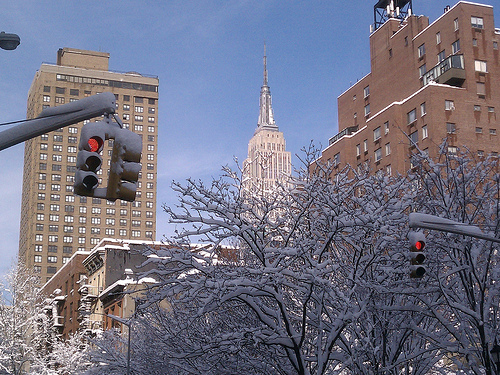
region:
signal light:
[74, 118, 138, 201]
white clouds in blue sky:
[154, 6, 196, 43]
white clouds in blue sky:
[277, 69, 316, 104]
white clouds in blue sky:
[180, 105, 203, 132]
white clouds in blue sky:
[183, 39, 220, 62]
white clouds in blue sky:
[166, 55, 210, 111]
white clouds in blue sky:
[181, 37, 230, 105]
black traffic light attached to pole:
[0, 95, 150, 211]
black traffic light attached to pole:
[407, 217, 498, 282]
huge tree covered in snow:
[141, 154, 389, 373]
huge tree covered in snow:
[313, 162, 453, 372]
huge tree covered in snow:
[41, 334, 88, 371]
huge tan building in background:
[230, 33, 292, 248]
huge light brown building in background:
[11, 48, 158, 298]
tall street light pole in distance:
[0, 32, 18, 54]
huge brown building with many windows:
[301, 0, 497, 234]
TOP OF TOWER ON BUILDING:
[248, 38, 283, 142]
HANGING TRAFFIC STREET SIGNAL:
[71, 116, 108, 211]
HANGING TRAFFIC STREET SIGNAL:
[103, 118, 146, 205]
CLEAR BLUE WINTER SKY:
[193, 22, 274, 64]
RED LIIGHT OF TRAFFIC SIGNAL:
[73, 124, 110, 154]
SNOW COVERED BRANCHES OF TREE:
[308, 243, 363, 295]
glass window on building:
[421, 103, 427, 119]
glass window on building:
[404, 107, 417, 124]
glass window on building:
[421, 122, 429, 139]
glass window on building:
[407, 129, 420, 144]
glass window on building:
[382, 116, 389, 135]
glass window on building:
[383, 141, 392, 156]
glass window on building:
[371, 143, 385, 165]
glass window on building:
[374, 123, 382, 144]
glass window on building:
[35, 223, 45, 235]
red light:
[75, 131, 110, 161]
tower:
[237, 63, 302, 184]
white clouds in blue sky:
[305, 16, 347, 54]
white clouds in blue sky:
[267, 49, 307, 76]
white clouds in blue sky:
[290, 55, 328, 103]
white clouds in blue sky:
[250, 11, 315, 46]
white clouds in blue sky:
[170, 28, 227, 60]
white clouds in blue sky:
[117, 0, 149, 31]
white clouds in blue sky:
[34, 5, 91, 32]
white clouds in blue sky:
[170, 61, 217, 111]